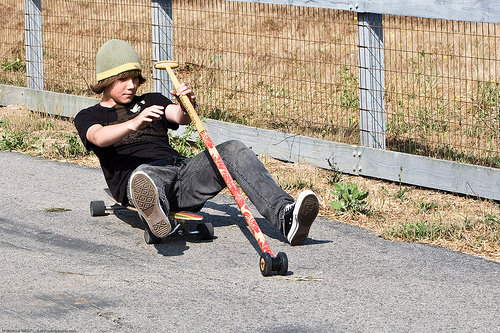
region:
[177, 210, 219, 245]
red, yellow, green tip of skateboard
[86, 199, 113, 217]
black skateboard wheel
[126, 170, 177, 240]
tan tread on bottom of sneaker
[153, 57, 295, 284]
skateboarder balance pole with wheels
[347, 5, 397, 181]
grey wooden fence post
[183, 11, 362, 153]
steel wire animal fencing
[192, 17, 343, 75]
golden tan field grass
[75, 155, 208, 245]
guy sitting on skateboard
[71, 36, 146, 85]
yellow and grey stocking cap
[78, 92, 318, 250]
guy with black t-shirt, shoes, grey jeans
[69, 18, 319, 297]
the boy is sitting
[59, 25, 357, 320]
the boy on a skateboard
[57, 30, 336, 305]
the boy is skateboarding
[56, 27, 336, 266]
the boy holding a pole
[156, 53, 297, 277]
the pole has wheels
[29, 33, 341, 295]
the boy wearing a beanie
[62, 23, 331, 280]
the boy beside the fence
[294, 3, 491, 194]
the fence is made of wood and metal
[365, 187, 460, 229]
the grass beside the fence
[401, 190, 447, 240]
the grass is dry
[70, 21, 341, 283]
the boy on the skateboard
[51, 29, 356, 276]
the boy wearing the beanie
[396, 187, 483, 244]
the grass beside the fence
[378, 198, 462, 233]
the grass is dry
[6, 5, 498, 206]
the fence is made of wood and wire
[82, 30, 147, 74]
the beanie is olive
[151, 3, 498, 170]
grey wood and metal mesh fence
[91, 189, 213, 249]
a skate board used for sitting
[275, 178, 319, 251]
black and white high top sneaker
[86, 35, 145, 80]
sage and yellow hat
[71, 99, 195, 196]
a black tee-shirt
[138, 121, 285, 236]
grey scrubby jeans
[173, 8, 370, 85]
dried brown grass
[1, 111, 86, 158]
sparse green from weeds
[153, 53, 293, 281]
long stick with two small wheels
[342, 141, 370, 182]
bolts holding fence together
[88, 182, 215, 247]
the skateboard under the boy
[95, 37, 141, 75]
the beanie on the boy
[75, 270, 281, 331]
the gray pavement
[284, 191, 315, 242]
the boy's left shoe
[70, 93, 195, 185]
the boy's short sleeved black shirt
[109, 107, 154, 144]
the design on the boy's shirt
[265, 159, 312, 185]
the brown grass near the boy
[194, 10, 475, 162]
the wired fence near the boy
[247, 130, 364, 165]
the wood on the bottom of the fence